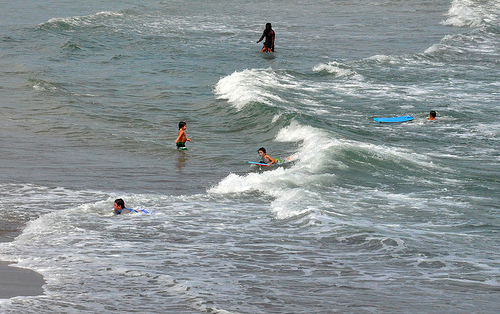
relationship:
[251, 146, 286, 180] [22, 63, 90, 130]
kid in water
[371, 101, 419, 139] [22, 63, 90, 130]
board in water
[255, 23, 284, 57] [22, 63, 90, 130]
man in water